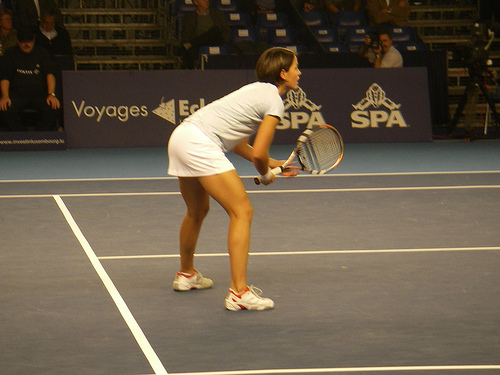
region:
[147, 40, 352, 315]
The woman is holding a tennis racket.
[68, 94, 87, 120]
The letter is white.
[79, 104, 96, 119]
The letter is white.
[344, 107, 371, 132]
The letter is white.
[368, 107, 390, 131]
The letter is white.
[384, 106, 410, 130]
The letter is white.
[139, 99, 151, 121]
The letter is white.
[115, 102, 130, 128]
The letter is white.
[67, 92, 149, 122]
Voyages written on a billboard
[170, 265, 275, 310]
White shoes on tennis player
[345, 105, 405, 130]
SPA written on right side of billboard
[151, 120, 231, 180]
Tennis player's white skirt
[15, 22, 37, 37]
Man in the crowds black hat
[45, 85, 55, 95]
Man in the crowd's watch on his wrist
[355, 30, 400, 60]
Man behind billboard taking pictures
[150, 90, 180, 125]
Triangle shape on the billboard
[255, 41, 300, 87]
Short hair do on womans head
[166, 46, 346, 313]
Woman holding onto tennis racket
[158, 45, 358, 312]
a female tennis player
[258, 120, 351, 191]
tennis racquet in woman's hand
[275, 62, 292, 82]
the right ear of the woman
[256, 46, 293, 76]
the woman's brown hair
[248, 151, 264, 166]
the woman's right elbow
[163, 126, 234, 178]
the woman's white tennis skirt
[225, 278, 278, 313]
white and red shoe on right foot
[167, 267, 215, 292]
white and red shoe on left foot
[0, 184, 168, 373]
white lines painted on ground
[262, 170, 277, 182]
wristband on woman's arm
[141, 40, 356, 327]
The woman is wearing a white tennis outfit.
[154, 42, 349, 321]
The woman's shoes are red and white.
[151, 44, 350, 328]
The woman is holding a tennis racket.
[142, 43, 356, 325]
The woman is bent over.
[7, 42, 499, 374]
The woman is standing on a tennis court.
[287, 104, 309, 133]
The letter is white.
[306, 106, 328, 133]
The letter is white.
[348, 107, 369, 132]
The letter is white.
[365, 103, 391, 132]
The letter is white.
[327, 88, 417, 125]
the sign says spa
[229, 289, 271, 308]
shoe on the foot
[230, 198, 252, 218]
knee on the leg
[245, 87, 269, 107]
the shirt is white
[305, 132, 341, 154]
top of the racket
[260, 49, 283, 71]
the hair is brown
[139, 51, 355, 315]
the woman is a tennis player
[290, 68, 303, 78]
nose of the woman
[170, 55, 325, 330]
A lady playing tennis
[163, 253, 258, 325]
A woman with red and white shoes on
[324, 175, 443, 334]
A grain white tennis court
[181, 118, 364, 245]
A woman with a orange and white tennis racket in her hand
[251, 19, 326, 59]
A group of blue empty chairs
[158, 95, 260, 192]
A woman wearing a white skirt